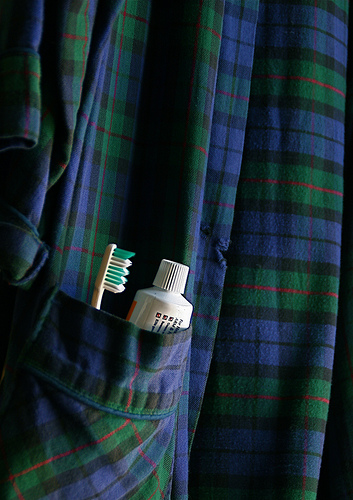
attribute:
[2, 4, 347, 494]
robe — flannel, warm, plaid, blue, red, green,, green, multicolored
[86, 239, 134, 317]
toothbrush — plastic, white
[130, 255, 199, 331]
toothpaste — white, red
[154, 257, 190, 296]
cap — white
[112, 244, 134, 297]
bristles — green, blue, white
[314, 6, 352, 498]
background — black